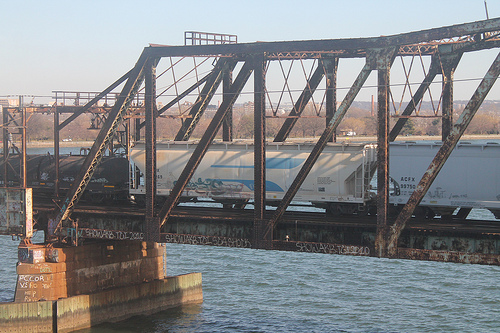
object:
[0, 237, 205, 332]
support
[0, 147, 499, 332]
water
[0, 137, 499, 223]
train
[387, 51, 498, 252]
beam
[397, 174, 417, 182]
black writing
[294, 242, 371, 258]
bridge graffi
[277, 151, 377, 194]
white train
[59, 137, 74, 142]
building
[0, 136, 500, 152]
shoreline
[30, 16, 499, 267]
bridge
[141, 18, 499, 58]
beam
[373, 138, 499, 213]
white car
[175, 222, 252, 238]
graffiti